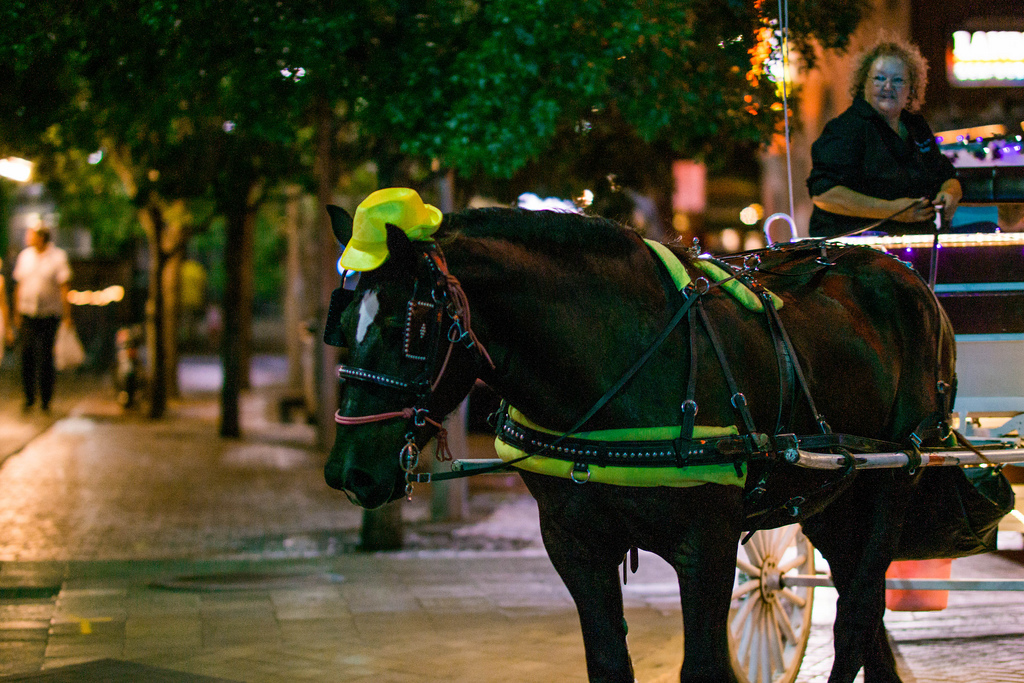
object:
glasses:
[870, 67, 914, 85]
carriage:
[719, 180, 1024, 683]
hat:
[333, 185, 443, 276]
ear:
[375, 220, 425, 273]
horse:
[313, 204, 961, 676]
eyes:
[314, 286, 361, 351]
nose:
[318, 461, 379, 491]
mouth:
[306, 455, 409, 511]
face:
[318, 267, 436, 486]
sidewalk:
[0, 359, 111, 572]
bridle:
[298, 278, 461, 474]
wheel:
[720, 510, 817, 683]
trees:
[121, 0, 345, 439]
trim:
[633, 218, 812, 322]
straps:
[490, 219, 863, 535]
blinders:
[321, 286, 442, 362]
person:
[13, 211, 72, 420]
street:
[0, 368, 1024, 677]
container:
[877, 543, 958, 615]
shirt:
[803, 103, 959, 238]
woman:
[799, 39, 967, 244]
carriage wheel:
[711, 485, 820, 682]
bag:
[67, 293, 142, 383]